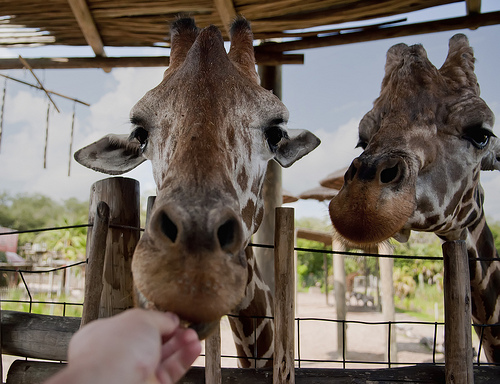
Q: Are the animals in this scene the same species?
A: Yes, all the animals are giraffes.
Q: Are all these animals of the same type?
A: Yes, all the animals are giraffes.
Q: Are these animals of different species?
A: No, all the animals are giraffes.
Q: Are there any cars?
A: No, there are no cars.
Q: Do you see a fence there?
A: Yes, there is a fence.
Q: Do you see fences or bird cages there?
A: Yes, there is a fence.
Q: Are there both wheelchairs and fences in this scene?
A: No, there is a fence but no wheelchairs.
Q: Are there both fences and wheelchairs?
A: No, there is a fence but no wheelchairs.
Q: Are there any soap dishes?
A: No, there are no soap dishes.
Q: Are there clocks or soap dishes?
A: No, there are no soap dishes or clocks.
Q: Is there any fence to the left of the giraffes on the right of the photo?
A: Yes, there is a fence to the left of the giraffes.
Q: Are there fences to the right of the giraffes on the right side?
A: No, the fence is to the left of the giraffes.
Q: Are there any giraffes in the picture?
A: Yes, there is a giraffe.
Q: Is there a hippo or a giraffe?
A: Yes, there is a giraffe.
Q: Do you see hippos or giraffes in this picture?
A: Yes, there is a giraffe.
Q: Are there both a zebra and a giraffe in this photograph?
A: No, there is a giraffe but no zebras.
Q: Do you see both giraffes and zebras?
A: No, there is a giraffe but no zebras.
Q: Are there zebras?
A: No, there are no zebras.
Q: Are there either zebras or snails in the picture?
A: No, there are no zebras or snails.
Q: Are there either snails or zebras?
A: No, there are no zebras or snails.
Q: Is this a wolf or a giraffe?
A: This is a giraffe.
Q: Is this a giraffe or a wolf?
A: This is a giraffe.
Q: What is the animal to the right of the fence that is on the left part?
A: The animal is a giraffe.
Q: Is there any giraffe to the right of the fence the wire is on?
A: Yes, there is a giraffe to the right of the fence.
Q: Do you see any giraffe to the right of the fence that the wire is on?
A: Yes, there is a giraffe to the right of the fence.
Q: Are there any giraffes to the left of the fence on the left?
A: No, the giraffe is to the right of the fence.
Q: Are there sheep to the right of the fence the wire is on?
A: No, there is a giraffe to the right of the fence.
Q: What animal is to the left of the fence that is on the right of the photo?
A: The animal is a giraffe.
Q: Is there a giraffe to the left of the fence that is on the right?
A: Yes, there is a giraffe to the left of the fence.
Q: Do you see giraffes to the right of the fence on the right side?
A: No, the giraffe is to the left of the fence.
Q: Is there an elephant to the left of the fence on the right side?
A: No, there is a giraffe to the left of the fence.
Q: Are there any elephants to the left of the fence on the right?
A: No, there is a giraffe to the left of the fence.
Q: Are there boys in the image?
A: No, there are no boys.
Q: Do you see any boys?
A: No, there are no boys.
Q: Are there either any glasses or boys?
A: No, there are no boys or glasses.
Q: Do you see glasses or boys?
A: No, there are no boys or glasses.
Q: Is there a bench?
A: No, there are no benches.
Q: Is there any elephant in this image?
A: No, there are no elephants.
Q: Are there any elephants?
A: No, there are no elephants.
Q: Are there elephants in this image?
A: No, there are no elephants.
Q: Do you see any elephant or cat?
A: No, there are no elephants or cats.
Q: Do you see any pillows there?
A: No, there are no pillows.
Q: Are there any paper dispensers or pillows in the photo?
A: No, there are no pillows or paper dispensers.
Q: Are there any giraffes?
A: Yes, there are giraffes.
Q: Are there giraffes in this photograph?
A: Yes, there are giraffes.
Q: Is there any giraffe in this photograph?
A: Yes, there are giraffes.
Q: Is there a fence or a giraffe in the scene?
A: Yes, there are giraffes.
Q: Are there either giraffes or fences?
A: Yes, there are giraffes.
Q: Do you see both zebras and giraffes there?
A: No, there are giraffes but no zebras.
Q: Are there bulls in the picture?
A: No, there are no bulls.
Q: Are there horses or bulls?
A: No, there are no bulls or horses.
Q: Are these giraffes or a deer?
A: These are giraffes.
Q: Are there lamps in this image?
A: No, there are no lamps.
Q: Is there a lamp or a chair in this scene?
A: No, there are no lamps or chairs.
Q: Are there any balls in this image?
A: No, there are no balls.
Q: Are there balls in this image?
A: No, there are no balls.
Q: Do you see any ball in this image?
A: No, there are no balls.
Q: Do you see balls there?
A: No, there are no balls.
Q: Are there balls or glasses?
A: No, there are no balls or glasses.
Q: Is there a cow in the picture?
A: No, there are no cows.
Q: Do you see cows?
A: No, there are no cows.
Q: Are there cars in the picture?
A: No, there are no cars.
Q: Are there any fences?
A: Yes, there is a fence.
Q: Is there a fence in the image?
A: Yes, there is a fence.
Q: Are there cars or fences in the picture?
A: Yes, there is a fence.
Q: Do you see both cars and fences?
A: No, there is a fence but no cars.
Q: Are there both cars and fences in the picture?
A: No, there is a fence but no cars.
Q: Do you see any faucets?
A: No, there are no faucets.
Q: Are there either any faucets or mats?
A: No, there are no faucets or mats.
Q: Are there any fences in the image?
A: Yes, there is a fence.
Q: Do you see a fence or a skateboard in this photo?
A: Yes, there is a fence.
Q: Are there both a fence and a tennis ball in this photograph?
A: No, there is a fence but no tennis balls.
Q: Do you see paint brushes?
A: No, there are no paint brushes.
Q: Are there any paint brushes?
A: No, there are no paint brushes.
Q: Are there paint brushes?
A: No, there are no paint brushes.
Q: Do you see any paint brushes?
A: No, there are no paint brushes.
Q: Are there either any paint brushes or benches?
A: No, there are no paint brushes or benches.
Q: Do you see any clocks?
A: No, there are no clocks.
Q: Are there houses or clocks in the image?
A: No, there are no clocks or houses.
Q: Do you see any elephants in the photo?
A: No, there are no elephants.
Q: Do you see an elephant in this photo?
A: No, there are no elephants.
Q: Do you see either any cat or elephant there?
A: No, there are no elephants or cats.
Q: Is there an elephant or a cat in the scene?
A: No, there are no elephants or cats.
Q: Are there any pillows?
A: No, there are no pillows.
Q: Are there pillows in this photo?
A: No, there are no pillows.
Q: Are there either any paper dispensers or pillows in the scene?
A: No, there are no pillows or paper dispensers.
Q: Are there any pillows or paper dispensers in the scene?
A: No, there are no pillows or paper dispensers.